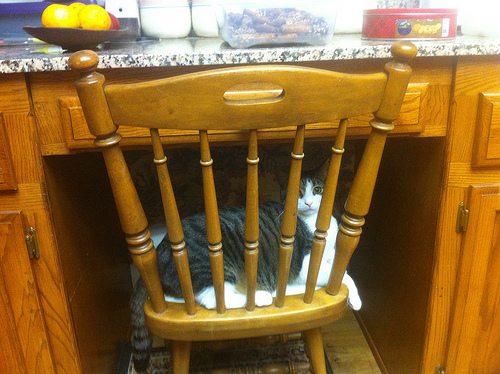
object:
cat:
[132, 157, 361, 374]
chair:
[67, 41, 419, 374]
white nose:
[305, 201, 312, 206]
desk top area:
[0, 32, 500, 62]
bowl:
[23, 27, 130, 49]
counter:
[0, 33, 500, 374]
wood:
[119, 85, 209, 119]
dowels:
[327, 115, 394, 294]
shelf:
[0, 42, 499, 76]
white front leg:
[342, 274, 362, 310]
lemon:
[80, 4, 110, 29]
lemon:
[42, 4, 79, 27]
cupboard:
[1, 72, 82, 373]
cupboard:
[421, 55, 500, 373]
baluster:
[150, 128, 195, 314]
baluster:
[200, 131, 226, 315]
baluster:
[246, 129, 258, 308]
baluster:
[276, 124, 305, 306]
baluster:
[304, 121, 346, 303]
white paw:
[254, 291, 273, 306]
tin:
[362, 10, 459, 42]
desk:
[0, 32, 500, 373]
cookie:
[281, 24, 311, 33]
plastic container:
[217, 4, 334, 48]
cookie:
[258, 25, 277, 33]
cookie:
[228, 13, 242, 29]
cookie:
[255, 34, 274, 42]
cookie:
[314, 19, 328, 35]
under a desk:
[43, 137, 446, 373]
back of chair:
[71, 40, 414, 373]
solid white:
[325, 240, 332, 282]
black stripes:
[221, 219, 245, 261]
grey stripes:
[181, 220, 208, 246]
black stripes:
[258, 207, 279, 234]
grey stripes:
[131, 313, 145, 326]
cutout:
[223, 81, 285, 105]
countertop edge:
[0, 38, 499, 72]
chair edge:
[143, 283, 348, 341]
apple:
[107, 12, 119, 29]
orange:
[70, 3, 87, 13]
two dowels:
[276, 119, 348, 306]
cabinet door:
[442, 185, 500, 374]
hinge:
[455, 202, 469, 234]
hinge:
[436, 364, 440, 373]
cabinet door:
[0, 212, 54, 374]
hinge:
[25, 227, 39, 260]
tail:
[129, 281, 150, 374]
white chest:
[305, 220, 340, 264]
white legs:
[195, 269, 246, 310]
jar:
[139, 0, 192, 38]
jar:
[192, 2, 219, 38]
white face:
[297, 187, 322, 214]